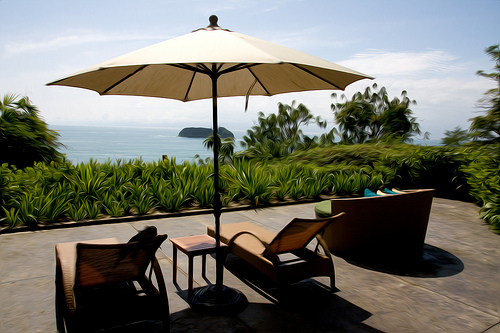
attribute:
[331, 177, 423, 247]
chair — round